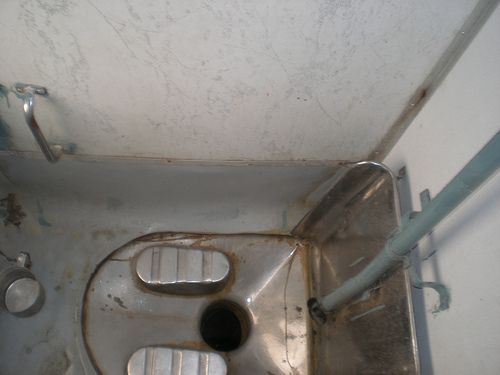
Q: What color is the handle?
A: Silver.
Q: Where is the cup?
A: On the floor.